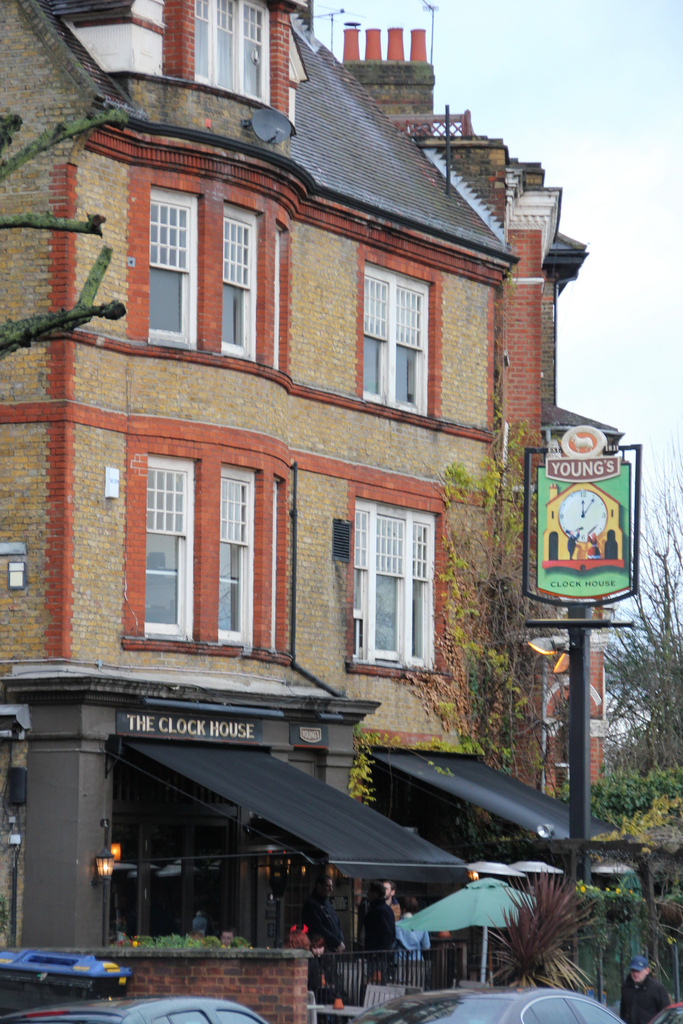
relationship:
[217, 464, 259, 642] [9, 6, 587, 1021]
window on building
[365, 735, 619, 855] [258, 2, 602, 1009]
awning on building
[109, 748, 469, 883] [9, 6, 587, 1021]
awning on building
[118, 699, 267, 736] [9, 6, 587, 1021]
lettering on building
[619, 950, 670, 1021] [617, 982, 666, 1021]
man wearing shirt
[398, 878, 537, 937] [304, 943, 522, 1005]
umbrella by railing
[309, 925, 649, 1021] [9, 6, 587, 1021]
railing beside building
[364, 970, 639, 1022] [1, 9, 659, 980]
car parked beside building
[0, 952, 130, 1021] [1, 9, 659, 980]
car parked beside building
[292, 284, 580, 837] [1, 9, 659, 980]
ivy growing on building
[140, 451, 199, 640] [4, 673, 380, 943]
window above entryway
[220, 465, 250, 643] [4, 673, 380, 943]
window above entryway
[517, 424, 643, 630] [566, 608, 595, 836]
sign on post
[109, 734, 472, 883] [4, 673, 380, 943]
awning on entryway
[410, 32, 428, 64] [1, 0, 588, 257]
smoke stack on roof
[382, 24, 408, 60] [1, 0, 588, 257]
smoke stack on roof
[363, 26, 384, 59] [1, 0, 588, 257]
smoke stack on roof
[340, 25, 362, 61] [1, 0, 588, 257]
smoke stack on roof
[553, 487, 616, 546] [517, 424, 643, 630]
clock on sign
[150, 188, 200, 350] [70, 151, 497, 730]
window on wall